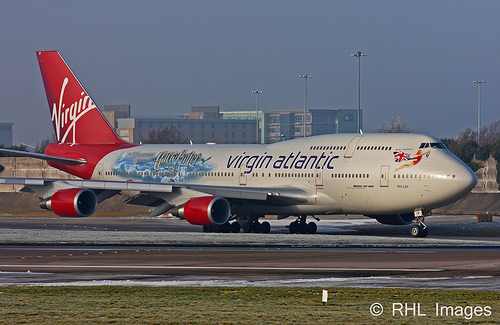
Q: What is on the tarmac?
A: Plane.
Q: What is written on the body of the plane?
A: Virgin atlantic.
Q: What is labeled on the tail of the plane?
A: Virgin.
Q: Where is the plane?
A: At an airport.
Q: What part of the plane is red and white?
A: The tail.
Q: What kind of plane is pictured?
A: Passenger plane.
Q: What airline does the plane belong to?
A: Virgin Atlantic.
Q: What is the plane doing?
A: Preparing for takeoff.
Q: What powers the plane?
A: Jet fuel.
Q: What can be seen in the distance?
A: Buildings.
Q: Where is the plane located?
A: On the runway.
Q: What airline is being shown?
A: Virgin atlantic.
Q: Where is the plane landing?
A: Airport.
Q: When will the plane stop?
A: Terminal.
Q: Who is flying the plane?
A: Pilot.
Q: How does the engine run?
A: Jet fuel.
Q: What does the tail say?
A: Virgin.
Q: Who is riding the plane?
A: Passengers.